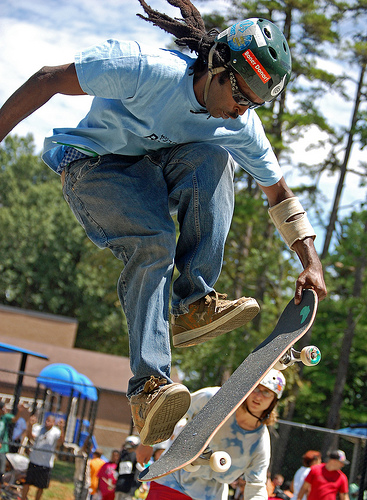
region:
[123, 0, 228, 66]
dude with dreads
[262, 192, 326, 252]
dude with wrist wrap that looks like ace bandage but isnt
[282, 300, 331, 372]
green paint on a wheel, green paint on a 'board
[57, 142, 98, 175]
blue+white gingham check boxers, but only a bit visible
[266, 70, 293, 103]
teardrop shape sticker @ front of helmet that has nought to do with crying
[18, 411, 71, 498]
two fists in the air, one pair of black shorts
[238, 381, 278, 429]
clear eyeglasses, lookse black chinstrap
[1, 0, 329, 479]
man jumping on a skateboard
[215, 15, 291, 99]
green helmet on the man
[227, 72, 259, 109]
black and white sunglasses on the man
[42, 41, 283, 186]
blue shirt on the man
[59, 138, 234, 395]
blue jeans on the man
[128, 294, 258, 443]
brown shoes on the man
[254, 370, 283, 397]
white helmet on the woman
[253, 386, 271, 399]
eyeglasses on the woman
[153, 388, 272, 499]
blue and white shirt on the woman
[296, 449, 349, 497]
man in a black and white hat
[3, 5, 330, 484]
A skateboarder performing a jump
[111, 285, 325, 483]
Feet above a skateboard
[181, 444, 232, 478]
The back wheels of a skateboard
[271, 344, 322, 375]
The front wheels of a skateboard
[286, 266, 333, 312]
A hand holding the top of a skateboard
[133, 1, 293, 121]
The head of a skateboarder in a helmet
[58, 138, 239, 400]
A baggy pair of blue jeans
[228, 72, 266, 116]
Black sunglasses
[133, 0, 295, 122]
A man's head with dreadlocks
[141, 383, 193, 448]
The bottom of a shoe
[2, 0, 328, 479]
a skateboarder performing a trick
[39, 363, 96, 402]
a blue canopy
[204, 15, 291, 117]
man wearing a green helmet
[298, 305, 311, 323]
a blue symbol on a skateboard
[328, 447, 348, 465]
man wearing a black and white cap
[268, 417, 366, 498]
a metal fence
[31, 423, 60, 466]
woman wearing a white shirt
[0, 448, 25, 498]
a baby stroller next to a woman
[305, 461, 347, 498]
man wearing a red shirt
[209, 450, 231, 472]
a white skateboard wheel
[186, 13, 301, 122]
green helmet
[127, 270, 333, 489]
black skateboard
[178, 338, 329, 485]
wheels on bottom of skateboard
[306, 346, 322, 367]
green paint on wheel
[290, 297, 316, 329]
green outline of country on surface of skateboard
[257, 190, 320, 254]
tan arm band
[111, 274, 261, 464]
brown and orange sneakers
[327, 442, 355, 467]
baseball cap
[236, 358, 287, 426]
white helmet and chin strap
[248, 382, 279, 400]
pair of eye glasses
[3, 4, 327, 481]
Guy doing tricks on a skateboard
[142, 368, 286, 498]
Guy with helmet watch skateboard tricks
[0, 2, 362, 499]
Exterior view, daytime, warmer months, likely.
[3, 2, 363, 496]
Close-up of airborne skateboarde, against public area with people.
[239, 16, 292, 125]
Green helmet with red sticker.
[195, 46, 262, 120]
Skater's head, showing chin strap, moustache, black goggles.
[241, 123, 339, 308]
Dark left arm, with elbow band, extended to grip skateboard.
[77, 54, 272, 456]
Tee-shirt, jeans and sneakers on skater.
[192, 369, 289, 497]
Bespectacled person, with white helmet, seen under skateboard wheels.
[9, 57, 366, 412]
White sky and closely packed trees, in distance.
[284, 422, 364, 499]
Metal fence and people in casual attire.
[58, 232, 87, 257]
green leaves on the tree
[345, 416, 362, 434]
green leaves on the tree